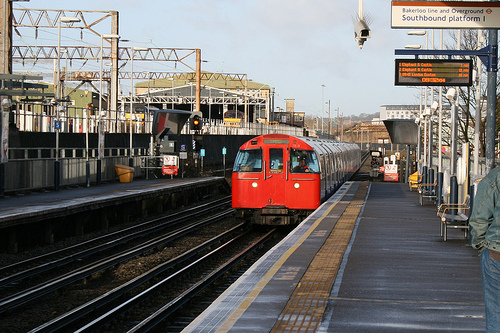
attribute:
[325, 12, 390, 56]
camera — white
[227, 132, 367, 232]
train — red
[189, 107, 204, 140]
light — yellow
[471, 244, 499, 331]
jeans — blue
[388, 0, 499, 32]
sign — white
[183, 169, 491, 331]
sidewalk — gray, concrete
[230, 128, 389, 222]
train — red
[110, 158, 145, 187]
bucket — yellow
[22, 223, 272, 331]
tracks — silver, metal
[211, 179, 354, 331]
line — yellow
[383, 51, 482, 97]
sign — black, orange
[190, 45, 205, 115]
pole — grey, metal